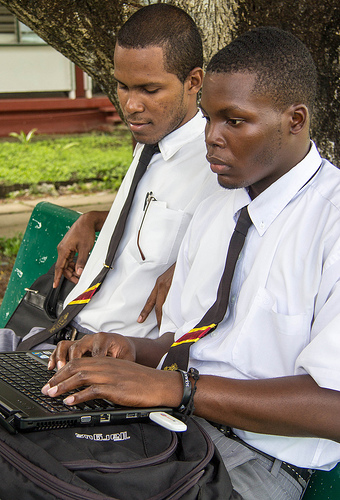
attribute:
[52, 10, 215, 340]
man — light skinned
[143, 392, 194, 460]
usb — white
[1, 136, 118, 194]
grass — green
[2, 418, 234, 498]
laptop bag — black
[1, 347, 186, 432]
laptop — black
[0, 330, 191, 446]
laptop — black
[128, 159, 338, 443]
shirt — white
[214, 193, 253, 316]
tie — black